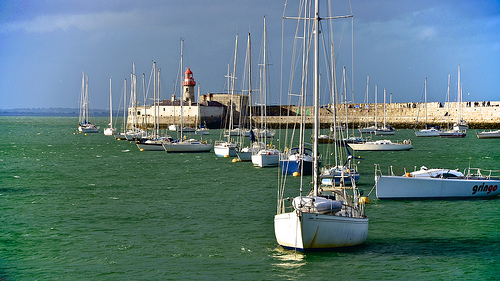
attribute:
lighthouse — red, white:
[182, 68, 194, 85]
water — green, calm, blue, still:
[1, 115, 498, 280]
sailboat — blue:
[284, 145, 321, 176]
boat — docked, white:
[349, 138, 413, 151]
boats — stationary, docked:
[74, 69, 295, 182]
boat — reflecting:
[267, 5, 372, 243]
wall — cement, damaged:
[241, 111, 500, 132]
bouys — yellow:
[232, 157, 238, 163]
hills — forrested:
[3, 104, 126, 115]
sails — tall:
[294, 5, 351, 211]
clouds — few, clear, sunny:
[2, 2, 490, 126]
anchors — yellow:
[360, 195, 370, 208]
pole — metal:
[311, 2, 321, 200]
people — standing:
[174, 115, 450, 122]